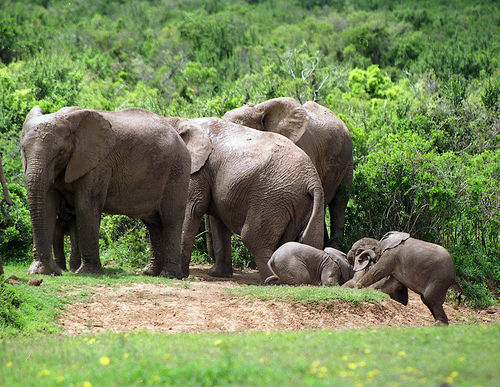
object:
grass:
[158, 336, 193, 348]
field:
[10, 263, 498, 382]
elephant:
[20, 104, 193, 278]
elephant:
[165, 117, 325, 282]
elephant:
[204, 95, 355, 259]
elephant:
[344, 231, 464, 325]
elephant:
[265, 241, 357, 288]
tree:
[348, 118, 441, 251]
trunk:
[25, 161, 61, 276]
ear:
[375, 231, 411, 256]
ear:
[62, 109, 117, 183]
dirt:
[77, 292, 257, 325]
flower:
[99, 355, 110, 364]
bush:
[429, 153, 500, 252]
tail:
[299, 180, 325, 248]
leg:
[76, 199, 101, 263]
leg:
[160, 207, 182, 269]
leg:
[209, 216, 230, 266]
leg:
[429, 305, 447, 323]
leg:
[182, 199, 203, 265]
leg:
[332, 184, 346, 244]